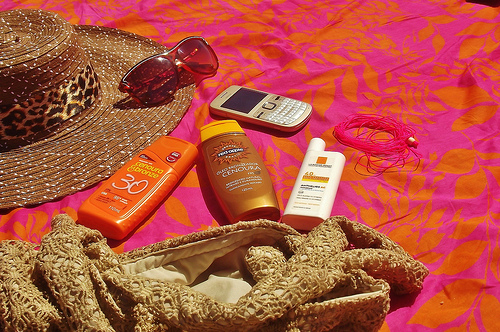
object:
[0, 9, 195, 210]
hat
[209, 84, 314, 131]
cell phone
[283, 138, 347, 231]
bottle care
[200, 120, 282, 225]
bottle care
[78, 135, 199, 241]
bottle care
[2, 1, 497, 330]
blanket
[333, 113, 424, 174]
bracelet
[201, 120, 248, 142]
top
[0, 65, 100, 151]
ribbon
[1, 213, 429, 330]
fabric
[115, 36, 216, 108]
shades